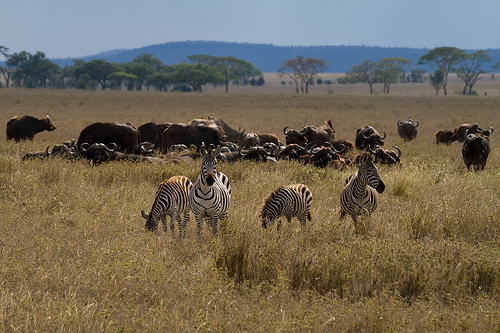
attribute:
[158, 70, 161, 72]
leaf — green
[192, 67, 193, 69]
leaf — green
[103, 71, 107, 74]
leaf — green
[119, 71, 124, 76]
leaf — green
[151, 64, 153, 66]
leaf — green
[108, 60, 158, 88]
tree — green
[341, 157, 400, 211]
zebra — standing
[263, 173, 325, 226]
zebra — standing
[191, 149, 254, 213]
zebra — standing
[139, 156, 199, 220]
zebra — standing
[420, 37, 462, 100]
tree — tall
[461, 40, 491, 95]
tree — tall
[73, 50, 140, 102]
trees — thick, tall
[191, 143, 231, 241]
zebra — black, white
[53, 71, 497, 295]
animals — together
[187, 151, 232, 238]
zebra — black, white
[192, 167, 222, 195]
nose — black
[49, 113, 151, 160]
animals — laying down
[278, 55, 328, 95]
tree — green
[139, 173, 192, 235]
zebra — black, white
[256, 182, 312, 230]
zebra — black, white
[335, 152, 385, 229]
zebra — black, white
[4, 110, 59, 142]
buffalo — traveling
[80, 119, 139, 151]
buffalo — traveling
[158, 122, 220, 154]
buffalo — traveling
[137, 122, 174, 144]
buffalo — traveling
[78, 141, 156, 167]
buffalo — traveling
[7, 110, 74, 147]
buffalo — dark, water, alone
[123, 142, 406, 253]
zebras — black, white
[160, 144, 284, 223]
zebra — standing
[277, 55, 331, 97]
trees — brown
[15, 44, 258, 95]
trees — brown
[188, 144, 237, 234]
zebra — alerted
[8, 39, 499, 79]
mountains — blue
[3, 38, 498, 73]
hazy land — gray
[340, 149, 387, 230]
animals — wild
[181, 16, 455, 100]
mountain — blue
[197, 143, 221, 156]
ears — pointed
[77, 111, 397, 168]
buffalo — dark , water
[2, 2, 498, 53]
sky — blue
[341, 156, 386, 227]
animal — wild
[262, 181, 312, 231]
animal — wild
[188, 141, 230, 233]
animal — wild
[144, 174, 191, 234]
animal — wild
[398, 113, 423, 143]
animal — wild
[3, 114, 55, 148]
bison — brown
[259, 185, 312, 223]
zebra — black, white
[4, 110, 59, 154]
cow — large, brown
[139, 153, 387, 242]
animals — wild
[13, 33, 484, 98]
trees — forest, small, green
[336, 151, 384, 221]
zebra — black, white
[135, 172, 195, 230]
zebra — black, white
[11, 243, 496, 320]
grass — thick, tan, tall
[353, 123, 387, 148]
bull — brown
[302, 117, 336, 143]
bull — brown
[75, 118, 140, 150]
bull — brown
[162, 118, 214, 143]
bull — brown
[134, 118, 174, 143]
bull — brown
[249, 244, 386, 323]
grass — brown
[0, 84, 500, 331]
grass — thick